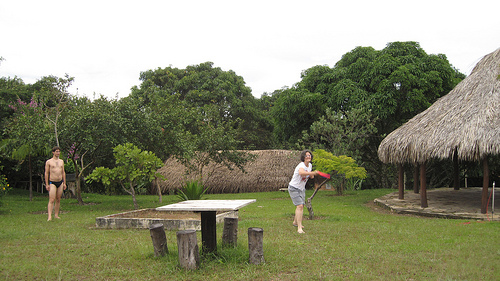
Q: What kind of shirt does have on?
A: None s naked.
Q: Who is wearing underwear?
A: The man.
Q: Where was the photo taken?
A: Outside somewhere.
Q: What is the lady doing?
A: Throwing a Frisbee.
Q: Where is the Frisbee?
A: In woman's hand.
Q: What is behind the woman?
A: Trees.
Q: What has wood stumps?
A: White table.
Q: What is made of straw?
A: The roof.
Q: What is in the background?
A: Many trees.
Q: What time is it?
A: Afternoon.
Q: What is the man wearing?
A: Speedo.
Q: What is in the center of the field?
A: Table.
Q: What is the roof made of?
A: Straw.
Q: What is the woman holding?
A: Frisbee.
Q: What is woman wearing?
A: Shirt and skirt.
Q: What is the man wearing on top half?
A: Nothing.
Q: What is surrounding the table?
A: Seats.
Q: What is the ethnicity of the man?
A: White.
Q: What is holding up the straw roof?
A: Log.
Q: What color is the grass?
A: Green.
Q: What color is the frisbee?
A: Red.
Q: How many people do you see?
A: Two.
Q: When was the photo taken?
A: Daytime.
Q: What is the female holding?
A: Frisbee.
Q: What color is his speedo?
A: Black.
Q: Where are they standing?
A: In the grass.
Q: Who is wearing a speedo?
A: Male.